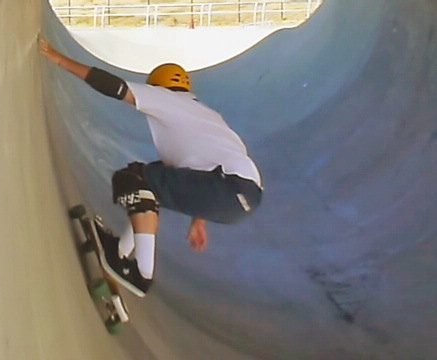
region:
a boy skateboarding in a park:
[8, 0, 386, 340]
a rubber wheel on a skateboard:
[95, 298, 122, 337]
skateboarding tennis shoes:
[83, 215, 165, 302]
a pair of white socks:
[113, 218, 162, 284]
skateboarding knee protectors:
[97, 153, 163, 220]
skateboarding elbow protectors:
[71, 54, 139, 114]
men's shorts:
[134, 150, 278, 232]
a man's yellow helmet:
[136, 55, 201, 100]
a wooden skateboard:
[56, 196, 138, 331]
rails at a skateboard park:
[77, 1, 282, 36]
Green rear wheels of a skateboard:
[76, 280, 134, 334]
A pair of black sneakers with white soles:
[90, 218, 164, 301]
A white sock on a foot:
[134, 229, 160, 275]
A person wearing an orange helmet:
[146, 53, 194, 102]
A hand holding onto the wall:
[29, 30, 76, 72]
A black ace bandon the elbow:
[81, 63, 132, 101]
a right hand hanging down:
[185, 214, 213, 260]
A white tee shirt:
[162, 103, 228, 157]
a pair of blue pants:
[195, 174, 246, 215]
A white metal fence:
[134, 7, 267, 28]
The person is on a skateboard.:
[26, 21, 291, 334]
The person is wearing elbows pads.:
[75, 59, 137, 110]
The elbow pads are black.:
[73, 56, 131, 109]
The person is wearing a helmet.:
[133, 61, 194, 100]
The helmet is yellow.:
[140, 56, 213, 105]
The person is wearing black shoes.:
[81, 216, 162, 308]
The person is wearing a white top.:
[113, 76, 275, 189]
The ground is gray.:
[200, 280, 295, 344]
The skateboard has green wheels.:
[53, 190, 134, 334]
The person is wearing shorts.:
[128, 134, 300, 235]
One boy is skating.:
[21, 22, 296, 322]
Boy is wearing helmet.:
[135, 59, 205, 133]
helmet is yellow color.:
[148, 67, 201, 103]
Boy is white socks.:
[105, 203, 169, 296]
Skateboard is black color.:
[70, 202, 143, 315]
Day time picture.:
[68, 8, 267, 127]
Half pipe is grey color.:
[255, 72, 397, 249]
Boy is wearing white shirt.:
[135, 81, 236, 170]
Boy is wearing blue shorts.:
[140, 154, 286, 221]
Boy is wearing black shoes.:
[97, 206, 158, 312]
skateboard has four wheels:
[68, 205, 119, 336]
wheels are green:
[79, 278, 131, 354]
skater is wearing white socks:
[122, 208, 166, 287]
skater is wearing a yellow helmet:
[143, 53, 183, 88]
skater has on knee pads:
[109, 152, 177, 220]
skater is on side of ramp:
[36, 96, 182, 280]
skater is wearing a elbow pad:
[81, 33, 154, 112]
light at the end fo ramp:
[82, 12, 301, 65]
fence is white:
[109, 1, 282, 20]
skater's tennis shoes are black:
[87, 212, 195, 320]